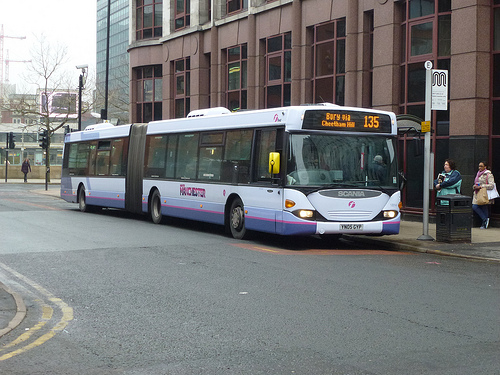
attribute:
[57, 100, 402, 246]
bus — long, white, stretched, purple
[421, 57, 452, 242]
signpost — white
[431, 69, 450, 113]
banner — white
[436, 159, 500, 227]
people — walking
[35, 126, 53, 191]
stoplights — black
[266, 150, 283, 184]
mirror — yellow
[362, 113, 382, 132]
numbers — orange, digital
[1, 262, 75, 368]
line — yellow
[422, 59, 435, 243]
pole — metal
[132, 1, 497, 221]
building — red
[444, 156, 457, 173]
hair — dark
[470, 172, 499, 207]
jacket — tan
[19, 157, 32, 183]
woman — walking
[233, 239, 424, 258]
marking — red